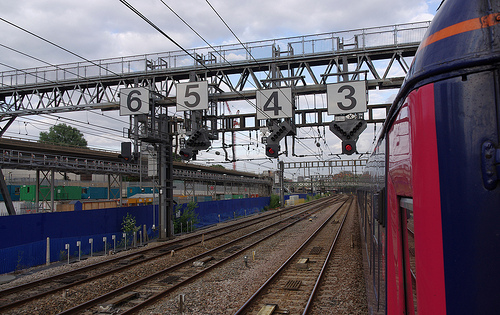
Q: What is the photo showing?
A: It is showing a walkway.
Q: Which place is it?
A: It is a walkway.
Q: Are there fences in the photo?
A: Yes, there is a fence.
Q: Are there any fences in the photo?
A: Yes, there is a fence.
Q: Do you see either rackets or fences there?
A: Yes, there is a fence.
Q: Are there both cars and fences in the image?
A: No, there is a fence but no cars.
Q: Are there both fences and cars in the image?
A: No, there is a fence but no cars.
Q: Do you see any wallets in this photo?
A: No, there are no wallets.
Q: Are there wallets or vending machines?
A: No, there are no wallets or vending machines.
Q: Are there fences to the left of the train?
A: Yes, there is a fence to the left of the train.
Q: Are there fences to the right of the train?
A: No, the fence is to the left of the train.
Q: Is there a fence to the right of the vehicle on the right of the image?
A: No, the fence is to the left of the train.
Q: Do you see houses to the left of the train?
A: No, there is a fence to the left of the train.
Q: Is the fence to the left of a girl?
A: No, the fence is to the left of the train.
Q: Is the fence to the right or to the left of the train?
A: The fence is to the left of the train.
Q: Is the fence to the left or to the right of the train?
A: The fence is to the left of the train.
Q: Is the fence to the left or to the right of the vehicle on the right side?
A: The fence is to the left of the train.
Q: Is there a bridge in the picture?
A: Yes, there is a bridge.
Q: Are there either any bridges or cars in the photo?
A: Yes, there is a bridge.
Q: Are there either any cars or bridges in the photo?
A: Yes, there is a bridge.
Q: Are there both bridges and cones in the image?
A: No, there is a bridge but no cones.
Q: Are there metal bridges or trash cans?
A: Yes, there is a metal bridge.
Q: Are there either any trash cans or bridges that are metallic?
A: Yes, the bridge is metallic.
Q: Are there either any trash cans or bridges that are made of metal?
A: Yes, the bridge is made of metal.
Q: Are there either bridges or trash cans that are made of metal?
A: Yes, the bridge is made of metal.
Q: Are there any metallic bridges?
A: Yes, there is a metal bridge.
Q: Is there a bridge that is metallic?
A: Yes, there is a bridge that is metallic.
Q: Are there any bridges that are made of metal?
A: Yes, there is a bridge that is made of metal.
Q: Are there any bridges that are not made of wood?
A: Yes, there is a bridge that is made of metal.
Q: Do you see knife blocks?
A: No, there are no knife blocks.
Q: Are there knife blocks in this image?
A: No, there are no knife blocks.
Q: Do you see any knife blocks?
A: No, there are no knife blocks.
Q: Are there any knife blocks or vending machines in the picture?
A: No, there are no knife blocks or vending machines.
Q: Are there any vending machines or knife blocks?
A: No, there are no knife blocks or vending machines.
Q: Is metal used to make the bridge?
A: Yes, the bridge is made of metal.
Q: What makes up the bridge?
A: The bridge is made of metal.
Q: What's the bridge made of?
A: The bridge is made of metal.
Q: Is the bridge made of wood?
A: No, the bridge is made of metal.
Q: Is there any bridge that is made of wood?
A: No, there is a bridge but it is made of metal.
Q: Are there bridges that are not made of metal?
A: No, there is a bridge but it is made of metal.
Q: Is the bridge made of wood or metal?
A: The bridge is made of metal.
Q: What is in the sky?
A: The clouds are in the sky.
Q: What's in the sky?
A: The clouds are in the sky.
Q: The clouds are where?
A: The clouds are in the sky.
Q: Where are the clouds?
A: The clouds are in the sky.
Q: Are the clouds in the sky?
A: Yes, the clouds are in the sky.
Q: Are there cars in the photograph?
A: No, there are no cars.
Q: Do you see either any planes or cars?
A: No, there are no cars or planes.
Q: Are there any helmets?
A: No, there are no helmets.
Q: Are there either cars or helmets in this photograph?
A: No, there are no helmets or cars.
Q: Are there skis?
A: No, there are no skis.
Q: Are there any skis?
A: No, there are no skis.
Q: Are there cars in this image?
A: No, there are no cars.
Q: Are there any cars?
A: No, there are no cars.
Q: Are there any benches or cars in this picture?
A: No, there are no cars or benches.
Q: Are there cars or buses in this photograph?
A: No, there are no cars or buses.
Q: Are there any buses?
A: No, there are no buses.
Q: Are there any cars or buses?
A: No, there are no buses or cars.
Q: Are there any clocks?
A: No, there are no clocks.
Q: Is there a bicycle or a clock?
A: No, there are no clocks or bicycles.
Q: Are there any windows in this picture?
A: Yes, there is a window.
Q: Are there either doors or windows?
A: Yes, there is a window.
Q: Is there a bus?
A: No, there are no buses.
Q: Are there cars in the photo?
A: No, there are no cars.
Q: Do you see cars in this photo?
A: No, there are no cars.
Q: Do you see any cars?
A: No, there are no cars.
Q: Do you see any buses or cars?
A: No, there are no cars or buses.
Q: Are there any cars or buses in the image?
A: No, there are no cars or buses.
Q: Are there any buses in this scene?
A: No, there are no buses.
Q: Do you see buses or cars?
A: No, there are no buses or cars.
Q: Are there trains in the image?
A: Yes, there is a train.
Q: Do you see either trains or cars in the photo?
A: Yes, there is a train.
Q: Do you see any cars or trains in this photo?
A: Yes, there is a train.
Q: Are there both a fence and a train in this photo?
A: Yes, there are both a train and a fence.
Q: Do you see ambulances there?
A: No, there are no ambulances.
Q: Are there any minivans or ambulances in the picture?
A: No, there are no ambulances or minivans.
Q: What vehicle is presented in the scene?
A: The vehicle is a train.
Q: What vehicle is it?
A: The vehicle is a train.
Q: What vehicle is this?
A: This is a train.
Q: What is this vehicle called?
A: This is a train.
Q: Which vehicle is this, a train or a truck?
A: This is a train.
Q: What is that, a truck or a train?
A: That is a train.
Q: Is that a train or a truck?
A: That is a train.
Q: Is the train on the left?
A: No, the train is on the right of the image.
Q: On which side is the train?
A: The train is on the right of the image.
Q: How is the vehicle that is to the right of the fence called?
A: The vehicle is a train.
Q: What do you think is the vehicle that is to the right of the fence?
A: The vehicle is a train.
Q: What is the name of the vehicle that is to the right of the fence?
A: The vehicle is a train.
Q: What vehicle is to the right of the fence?
A: The vehicle is a train.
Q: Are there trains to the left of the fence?
A: No, the train is to the right of the fence.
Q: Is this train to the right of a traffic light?
A: No, the train is to the right of the fence.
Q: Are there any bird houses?
A: No, there are no bird houses.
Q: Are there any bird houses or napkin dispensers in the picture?
A: No, there are no bird houses or napkin dispensers.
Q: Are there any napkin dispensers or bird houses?
A: No, there are no bird houses or napkin dispensers.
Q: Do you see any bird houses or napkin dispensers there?
A: No, there are no bird houses or napkin dispensers.